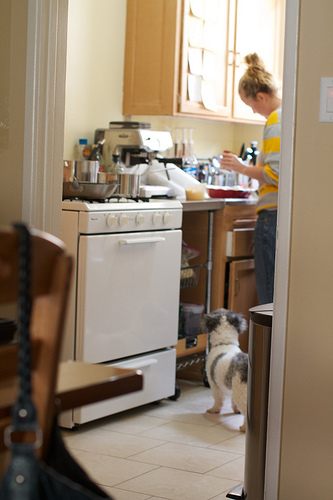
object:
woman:
[220, 52, 281, 306]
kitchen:
[0, 1, 333, 497]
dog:
[202, 303, 249, 435]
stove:
[61, 198, 184, 428]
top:
[255, 108, 282, 215]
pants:
[253, 210, 275, 307]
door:
[72, 230, 181, 369]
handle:
[119, 235, 168, 246]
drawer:
[72, 346, 177, 428]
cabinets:
[122, 0, 284, 128]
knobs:
[106, 215, 120, 232]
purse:
[5, 220, 114, 499]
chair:
[0, 223, 75, 466]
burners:
[64, 194, 152, 206]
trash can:
[235, 301, 278, 499]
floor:
[61, 374, 247, 499]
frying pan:
[64, 176, 121, 200]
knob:
[135, 212, 149, 228]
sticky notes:
[185, 1, 226, 115]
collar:
[208, 338, 241, 350]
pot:
[96, 168, 143, 200]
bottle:
[74, 137, 90, 161]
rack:
[176, 196, 223, 401]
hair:
[235, 49, 284, 98]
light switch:
[318, 77, 333, 120]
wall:
[263, 0, 332, 499]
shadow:
[160, 408, 246, 446]